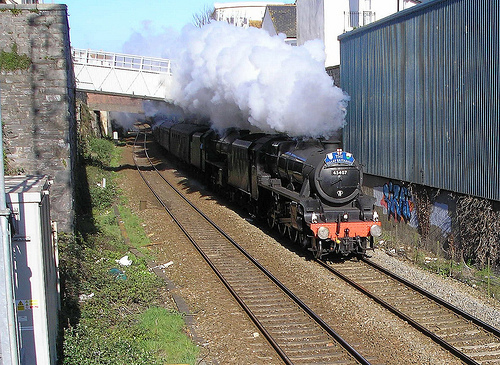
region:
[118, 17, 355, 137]
Steam from the funnel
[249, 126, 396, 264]
A black steam engine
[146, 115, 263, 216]
the engine pulls cars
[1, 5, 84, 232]
A gray stone wall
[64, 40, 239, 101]
A white metal bridge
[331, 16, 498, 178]
A blue metal wall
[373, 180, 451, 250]
Someone has spray painted graffiti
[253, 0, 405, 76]
Some white houses next to the track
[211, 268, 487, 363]
train tracks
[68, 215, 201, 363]
green grass and vines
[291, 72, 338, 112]
part of a smoke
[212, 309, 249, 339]
part of a ground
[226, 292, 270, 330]
edge of a rail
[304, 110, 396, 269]
part of a train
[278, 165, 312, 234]
edge of a train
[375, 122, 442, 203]
edge of a fence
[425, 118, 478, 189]
part of a fence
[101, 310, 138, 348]
part of some grass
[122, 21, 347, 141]
White smoke coming from a train stack.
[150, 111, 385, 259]
An orange and mostly black colored train.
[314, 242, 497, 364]
Tracks in front of a moving train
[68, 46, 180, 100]
A white bridge over the tracks.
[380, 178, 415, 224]
Black and blue graffiti on a wall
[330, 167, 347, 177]
Numbers on the front of a train.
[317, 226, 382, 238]
Two round lights on the front of a train.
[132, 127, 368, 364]
First set of tracks with no train on it.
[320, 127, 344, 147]
A black train stack.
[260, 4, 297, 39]
A pitched roof above the smoke.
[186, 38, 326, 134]
White smoke on top of train.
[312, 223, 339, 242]
White train light on left end of train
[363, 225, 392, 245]
White light on right end of train.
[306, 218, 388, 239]
Red bottom on front of train.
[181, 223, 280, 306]
Black copper train tracks.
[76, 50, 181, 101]
White overpass above train.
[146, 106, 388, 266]
Long black locomotive train.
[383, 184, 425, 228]
Blue graffitti on wall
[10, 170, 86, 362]
White power source left of train.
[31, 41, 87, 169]
Greyish white brick wall.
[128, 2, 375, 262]
smoke billowing from train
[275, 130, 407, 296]
orange on train car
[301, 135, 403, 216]
blue on train car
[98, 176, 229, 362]
trash along the train tracks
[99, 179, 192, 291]
grass and weeds along tracks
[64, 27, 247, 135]
bridge over train tracks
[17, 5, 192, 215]
stone wall near train tracks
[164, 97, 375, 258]
black train cars on track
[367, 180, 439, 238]
blue writing on sign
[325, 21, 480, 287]
building next to tracks